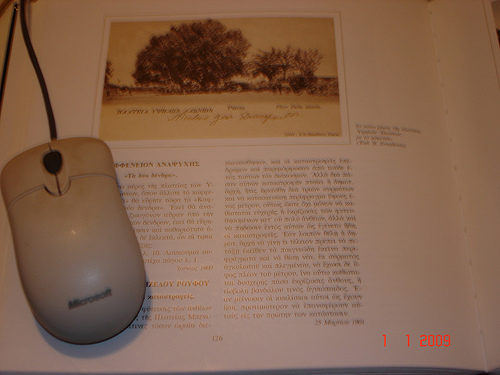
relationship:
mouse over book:
[1, 137, 147, 346] [0, 1, 499, 374]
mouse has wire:
[1, 137, 147, 346] [18, 0, 59, 142]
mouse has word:
[1, 137, 147, 346] [68, 288, 112, 310]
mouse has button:
[1, 137, 147, 346] [49, 137, 118, 196]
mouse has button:
[1, 137, 147, 346] [1, 143, 60, 208]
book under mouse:
[0, 1, 499, 374] [1, 137, 147, 346]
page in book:
[2, 0, 487, 374] [0, 1, 499, 374]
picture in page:
[97, 17, 342, 142] [2, 0, 487, 374]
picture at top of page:
[97, 17, 342, 142] [2, 0, 487, 374]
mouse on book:
[1, 137, 147, 346] [0, 1, 499, 374]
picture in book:
[97, 17, 342, 142] [0, 1, 499, 374]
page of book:
[2, 0, 487, 374] [0, 1, 499, 374]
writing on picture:
[116, 104, 320, 122] [97, 17, 342, 142]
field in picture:
[98, 76, 342, 136] [97, 17, 342, 142]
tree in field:
[132, 19, 253, 93] [98, 76, 342, 136]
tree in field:
[294, 48, 323, 76] [98, 76, 342, 136]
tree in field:
[105, 60, 115, 84] [98, 76, 342, 136]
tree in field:
[274, 49, 294, 80] [98, 76, 342, 136]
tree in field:
[244, 47, 284, 81] [98, 76, 342, 136]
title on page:
[114, 162, 200, 169] [2, 0, 487, 374]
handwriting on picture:
[169, 109, 299, 122] [97, 17, 342, 142]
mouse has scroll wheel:
[1, 137, 147, 346] [43, 151, 62, 174]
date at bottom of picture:
[383, 333, 451, 347] [0, 1, 500, 374]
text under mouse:
[111, 158, 366, 329] [1, 137, 147, 346]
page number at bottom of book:
[211, 335, 223, 342] [0, 1, 499, 374]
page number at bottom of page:
[211, 335, 223, 342] [2, 0, 487, 374]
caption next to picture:
[355, 123, 420, 148] [97, 17, 342, 142]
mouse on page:
[1, 137, 147, 346] [2, 0, 487, 374]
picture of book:
[0, 1, 500, 374] [0, 1, 499, 374]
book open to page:
[0, 1, 499, 374] [2, 0, 487, 374]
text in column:
[111, 158, 366, 329] [114, 162, 214, 329]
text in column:
[111, 158, 366, 329] [223, 158, 365, 327]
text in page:
[111, 158, 366, 329] [2, 0, 487, 374]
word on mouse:
[68, 288, 112, 310] [1, 137, 147, 346]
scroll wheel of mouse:
[43, 151, 62, 174] [1, 137, 147, 346]